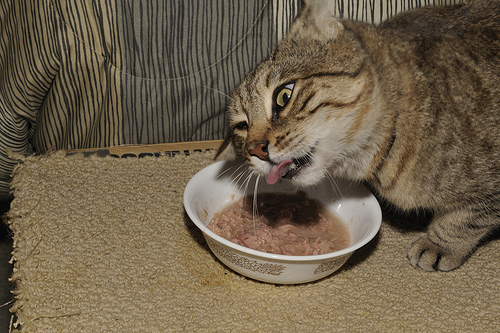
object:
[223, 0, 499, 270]
cat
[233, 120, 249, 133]
right eye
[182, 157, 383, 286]
meal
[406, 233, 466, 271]
paw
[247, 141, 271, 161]
nose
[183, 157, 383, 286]
bowl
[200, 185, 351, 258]
food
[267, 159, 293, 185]
tongue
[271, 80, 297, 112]
left eye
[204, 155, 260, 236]
whiskers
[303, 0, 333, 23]
ears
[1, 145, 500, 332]
rug